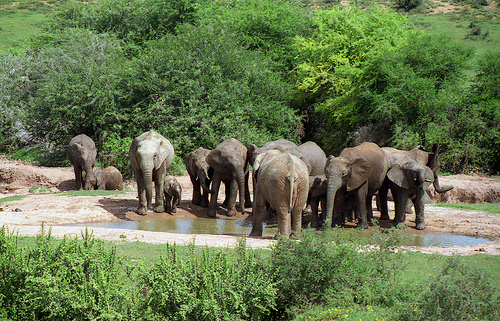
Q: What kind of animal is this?
A: Elephant.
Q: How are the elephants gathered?
A: In a herd.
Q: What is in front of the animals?
A: Water hole.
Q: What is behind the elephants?
A: Trees and foliage.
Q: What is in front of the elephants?
A: Green grass.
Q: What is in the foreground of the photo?
A: Trees , brush, bushes.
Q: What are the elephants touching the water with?
A: Feet and trunks.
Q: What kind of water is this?
A: Brown tinted water.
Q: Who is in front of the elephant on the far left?
A: Baby elephant.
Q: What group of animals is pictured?
A: Elephants.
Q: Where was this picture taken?
A: In the wild.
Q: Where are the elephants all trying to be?
A: In the water.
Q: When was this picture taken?
A: Afternoon.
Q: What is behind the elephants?
A: Tree's.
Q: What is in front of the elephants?
A: Bushes.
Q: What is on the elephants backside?
A: Tail.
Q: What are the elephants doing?
A: Drinking.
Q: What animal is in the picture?
A: Elephant.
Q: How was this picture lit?
A: Sunlight.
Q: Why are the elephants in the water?
A: They need to drink.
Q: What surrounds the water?
A: Sand.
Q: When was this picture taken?
A: Daytime.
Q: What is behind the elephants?
A: Trees.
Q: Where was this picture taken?
A: In the field.